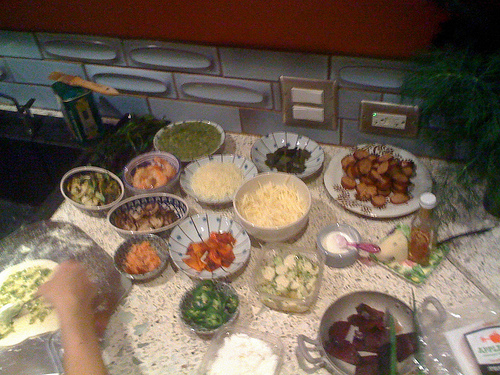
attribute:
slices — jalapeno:
[188, 290, 231, 328]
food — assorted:
[62, 123, 423, 373]